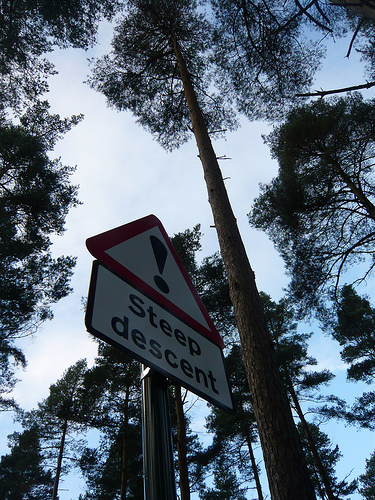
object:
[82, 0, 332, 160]
tree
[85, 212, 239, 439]
sign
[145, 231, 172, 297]
punctuation mark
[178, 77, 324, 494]
trunk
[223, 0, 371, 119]
tree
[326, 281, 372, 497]
tree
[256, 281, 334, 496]
tree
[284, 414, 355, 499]
tree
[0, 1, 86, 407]
tree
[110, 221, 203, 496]
tree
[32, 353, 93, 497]
tree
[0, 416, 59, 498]
tree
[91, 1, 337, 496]
trees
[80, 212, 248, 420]
sign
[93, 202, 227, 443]
sign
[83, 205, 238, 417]
tablecloth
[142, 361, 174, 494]
post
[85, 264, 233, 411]
sign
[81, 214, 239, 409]
sign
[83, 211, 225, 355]
triangle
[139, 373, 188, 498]
pole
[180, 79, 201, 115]
bark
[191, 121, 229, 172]
bark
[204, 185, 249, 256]
bark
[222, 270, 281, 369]
bark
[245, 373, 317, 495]
bark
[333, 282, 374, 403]
tree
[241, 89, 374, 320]
tree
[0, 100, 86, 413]
tree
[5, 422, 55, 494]
tree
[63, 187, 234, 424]
sign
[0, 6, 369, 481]
sky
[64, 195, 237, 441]
sign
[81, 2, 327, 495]
tree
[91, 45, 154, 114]
branch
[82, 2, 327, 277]
tree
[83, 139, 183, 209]
sky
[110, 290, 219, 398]
words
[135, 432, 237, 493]
ground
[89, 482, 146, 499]
brown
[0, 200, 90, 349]
tree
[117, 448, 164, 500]
bottom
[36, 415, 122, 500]
leaves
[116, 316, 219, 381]
"steep descent"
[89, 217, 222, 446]
sign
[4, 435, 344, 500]
forest